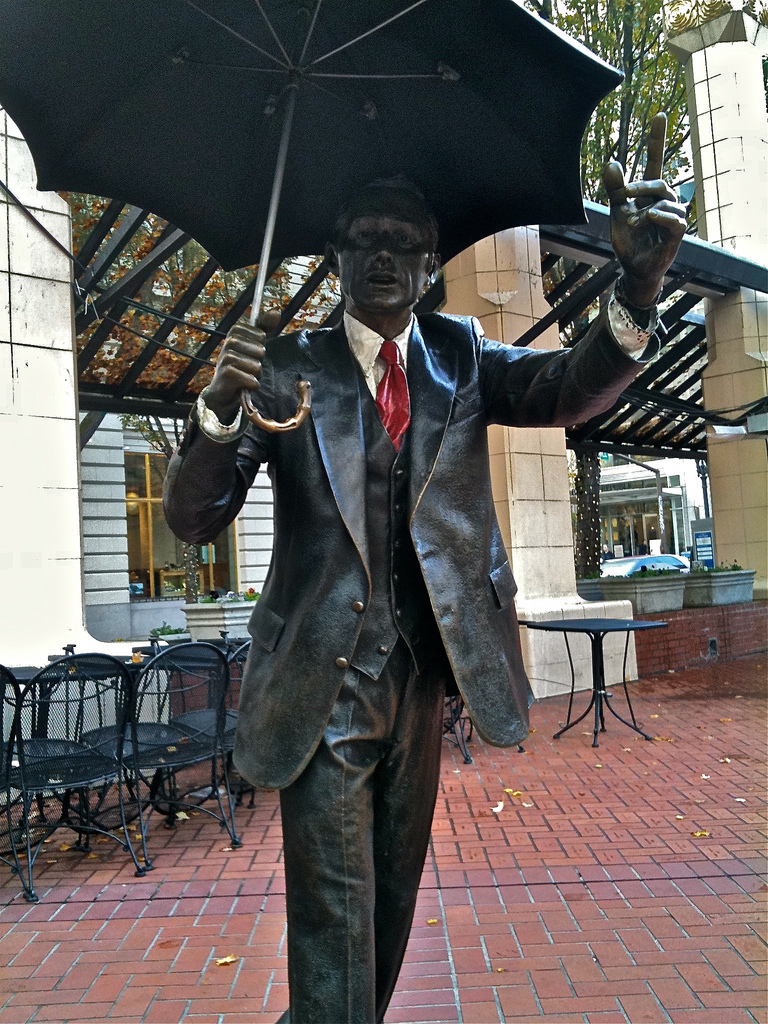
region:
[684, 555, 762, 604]
Silver container with green plants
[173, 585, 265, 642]
Gray colored planter with flowers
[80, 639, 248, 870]
All black metal chair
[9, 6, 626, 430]
Black umbrella with bronze handle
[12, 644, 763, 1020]
Red brick sidewalk with white and black filler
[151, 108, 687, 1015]
Metal statue with red tie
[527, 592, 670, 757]
Black topped table with black legs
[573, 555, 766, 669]
Two flower planters on red brick wall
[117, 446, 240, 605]
Window with brown frame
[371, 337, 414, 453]
Red tie on statue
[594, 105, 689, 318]
Left hand of statue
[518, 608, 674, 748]
Empty table on patio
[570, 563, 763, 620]
Silver tubs for planters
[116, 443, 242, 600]
Window in building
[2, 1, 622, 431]
Black umbrella is open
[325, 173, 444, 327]
Head of the statue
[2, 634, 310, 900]
Group of empty chairs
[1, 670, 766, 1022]
Red brick patio and walkway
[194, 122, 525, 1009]
bronze statue holding a umbrella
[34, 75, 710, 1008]
bronze statue holding a umbrella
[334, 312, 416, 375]
statue with white shirt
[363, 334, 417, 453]
Red tie on statue.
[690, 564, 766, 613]
Long pot of flowers.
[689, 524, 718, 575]
Blue sign in the background.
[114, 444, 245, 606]
Window on the building.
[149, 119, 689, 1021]
Decorative statue of a man.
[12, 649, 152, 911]
Black metal patio chair.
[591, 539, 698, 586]
Car parked in the background.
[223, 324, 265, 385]
the statues hand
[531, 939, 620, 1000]
the brick ground is red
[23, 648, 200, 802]
black chairs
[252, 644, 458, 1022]
the mans legs below torso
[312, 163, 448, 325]
the mans head above shoulders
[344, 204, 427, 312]
the facial area of the mans head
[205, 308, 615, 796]
the mans shirt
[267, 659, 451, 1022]
the mans pants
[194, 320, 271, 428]
the mans hand at end of arm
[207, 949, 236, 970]
a leaf on the ground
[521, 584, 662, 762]
a black table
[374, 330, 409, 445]
a red tie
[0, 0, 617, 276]
an umbrella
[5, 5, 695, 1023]
statue of business man in a suit with umbrella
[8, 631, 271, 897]
black metal mesh chairs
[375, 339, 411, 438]
a red neck tie on a statue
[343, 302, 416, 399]
white dress shirt painted on the statue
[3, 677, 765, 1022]
red brick sidewalk area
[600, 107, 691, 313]
a raised index finger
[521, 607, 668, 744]
a table with no chairs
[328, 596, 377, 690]
two buttons of a suit coat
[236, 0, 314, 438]
curved handle of an umbrella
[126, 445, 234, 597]
window of a grey building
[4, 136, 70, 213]
A tile in a wall.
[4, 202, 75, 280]
A tile in a wall.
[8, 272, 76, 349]
A tile in a wall.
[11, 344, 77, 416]
A tile in a wall.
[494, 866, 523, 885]
A brick in a sidewalk.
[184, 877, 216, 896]
A brick in a sidewalk.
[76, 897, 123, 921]
A brick in a sidewalk.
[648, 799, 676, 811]
A brick in a sidewalk.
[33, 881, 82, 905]
A brick in a sidewalk.